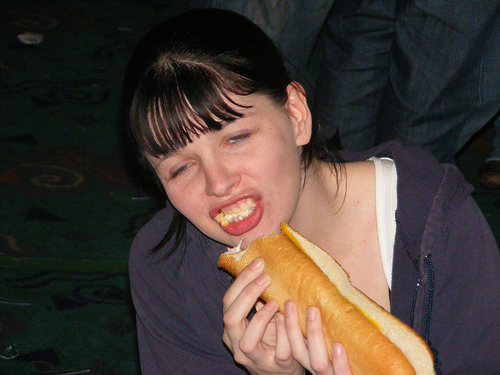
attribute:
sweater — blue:
[124, 131, 495, 373]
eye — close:
[165, 158, 194, 179]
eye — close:
[215, 125, 252, 150]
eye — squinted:
[165, 157, 205, 182]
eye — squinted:
[216, 124, 262, 148]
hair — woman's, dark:
[113, 4, 348, 263]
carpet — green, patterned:
[0, 2, 140, 369]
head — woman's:
[130, 8, 312, 249]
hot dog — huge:
[182, 200, 440, 362]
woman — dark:
[111, 57, 478, 349]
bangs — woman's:
[101, 42, 298, 153]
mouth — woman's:
[210, 190, 264, 236]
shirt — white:
[366, 138, 403, 260]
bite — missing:
[214, 223, 299, 259]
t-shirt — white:
[370, 151, 400, 284]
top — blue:
[121, 148, 498, 373]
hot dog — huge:
[209, 217, 443, 373]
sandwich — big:
[219, 223, 443, 372]